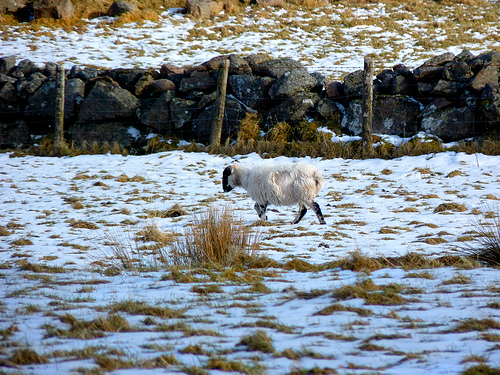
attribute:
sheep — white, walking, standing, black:
[221, 157, 331, 228]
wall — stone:
[11, 57, 496, 153]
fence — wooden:
[49, 54, 93, 162]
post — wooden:
[216, 54, 235, 161]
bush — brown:
[240, 110, 338, 161]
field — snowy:
[24, 128, 444, 320]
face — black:
[219, 166, 232, 196]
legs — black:
[253, 198, 331, 228]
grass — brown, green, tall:
[103, 229, 144, 282]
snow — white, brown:
[162, 161, 192, 181]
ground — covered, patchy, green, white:
[260, 221, 328, 252]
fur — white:
[296, 177, 315, 205]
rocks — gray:
[0, 55, 50, 120]